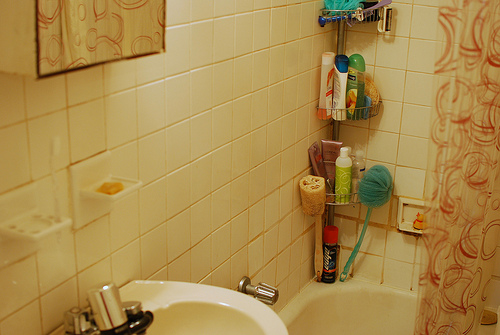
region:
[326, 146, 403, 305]
a green shower scrub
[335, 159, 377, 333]
a green shower scrub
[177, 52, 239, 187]
the wall is tiled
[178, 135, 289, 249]
the wall is tiled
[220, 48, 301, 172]
the wall is tiled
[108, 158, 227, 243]
the wall is tiled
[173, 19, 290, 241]
The tile on the wall is white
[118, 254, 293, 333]
The sink is the color white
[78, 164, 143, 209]
The soap holder is white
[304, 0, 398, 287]
The shower caddy against the wall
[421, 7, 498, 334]
The shower curtain has red on it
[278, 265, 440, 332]
The bath tub is white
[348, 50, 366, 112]
The shower gel in the container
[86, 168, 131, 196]
The soap is the color yellow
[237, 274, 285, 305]
The shower handle is silver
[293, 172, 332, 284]
The loofah is the color beige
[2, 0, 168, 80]
metal medicine cabinet with a mirrored front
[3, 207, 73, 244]
empty ceramic toothbrush holder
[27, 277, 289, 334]
white ceramic bathroom sink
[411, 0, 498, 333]
clear shower curtain with red swirl design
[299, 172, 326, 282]
sea sponge loofah on a wooden handle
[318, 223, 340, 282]
can of shave gel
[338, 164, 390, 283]
blue back scrub poof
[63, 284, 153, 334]
sinks silver faucet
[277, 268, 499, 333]
white ceramic bath tub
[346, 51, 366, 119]
bottle of green body wash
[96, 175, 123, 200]
yellow bar of soap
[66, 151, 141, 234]
dish on the wall holding the soap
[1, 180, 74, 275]
empty toothbrush holder attached to the wall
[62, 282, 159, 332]
faucet for the sink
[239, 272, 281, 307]
knob for the tub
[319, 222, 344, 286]
red and black bottle of shave gel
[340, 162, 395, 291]
green body scrubber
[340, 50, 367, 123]
green bottle of body wash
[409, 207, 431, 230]
yellow and red rubber ducky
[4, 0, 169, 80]
mirror attached to the wall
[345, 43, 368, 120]
the bottle is green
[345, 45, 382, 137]
the bottle is green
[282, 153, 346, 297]
a loofah leaning on the wall